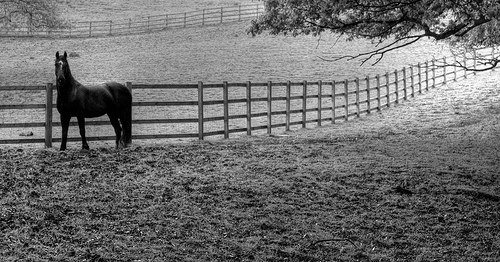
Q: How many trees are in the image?
A: 1.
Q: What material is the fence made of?
A: Wood.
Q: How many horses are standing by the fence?
A: 1.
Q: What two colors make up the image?
A: Black and white.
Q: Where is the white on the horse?
A: On its face.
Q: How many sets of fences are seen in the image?
A: 2.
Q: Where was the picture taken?
A: In a pasture.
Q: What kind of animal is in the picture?
A: A horse.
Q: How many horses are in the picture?
A: 1.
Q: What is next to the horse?
A: A fence.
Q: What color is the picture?
A: Black and white.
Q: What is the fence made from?
A: Wood.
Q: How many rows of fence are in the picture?
A: 2.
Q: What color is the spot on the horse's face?
A: White.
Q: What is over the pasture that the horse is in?
A: A tree.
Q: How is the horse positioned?
A: Standing.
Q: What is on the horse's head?
A: White spot.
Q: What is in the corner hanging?
A: Tree.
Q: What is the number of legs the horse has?
A: Four.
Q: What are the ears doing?
A: Pointing up.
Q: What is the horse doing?
A: Standing.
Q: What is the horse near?
A: Fence.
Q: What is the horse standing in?
A: Field of grass.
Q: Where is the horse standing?
A: Field.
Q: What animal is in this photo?
A: Horse.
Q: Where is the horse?
A: Outside in a field.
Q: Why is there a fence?
A: To contain the animal.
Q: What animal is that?
A: A horse.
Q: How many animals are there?
A: One.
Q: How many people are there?
A: None.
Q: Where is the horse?
A: On the field.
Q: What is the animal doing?
A: Standing.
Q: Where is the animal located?
A: By the fence.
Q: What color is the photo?
A: Black and white.